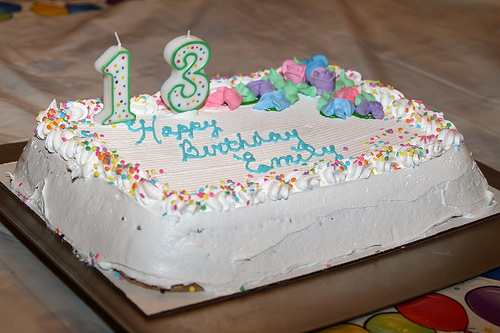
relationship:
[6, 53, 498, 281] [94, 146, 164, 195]
cake with sprinkles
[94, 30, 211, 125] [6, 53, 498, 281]
13 on cake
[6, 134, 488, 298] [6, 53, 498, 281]
frosting on cake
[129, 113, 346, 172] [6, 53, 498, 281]
words on cake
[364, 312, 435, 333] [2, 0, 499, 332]
balloon on table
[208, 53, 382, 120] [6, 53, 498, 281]
roses on cake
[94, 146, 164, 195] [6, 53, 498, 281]
sprinkles on cake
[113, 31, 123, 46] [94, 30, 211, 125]
wicker on 13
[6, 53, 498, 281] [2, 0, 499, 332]
cake on table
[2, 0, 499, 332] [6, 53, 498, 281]
table with cake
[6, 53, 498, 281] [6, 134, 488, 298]
cake with frosting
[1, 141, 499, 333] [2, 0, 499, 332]
cake pan on table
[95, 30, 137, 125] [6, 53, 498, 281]
1 on cake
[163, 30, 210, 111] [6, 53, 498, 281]
3 on cake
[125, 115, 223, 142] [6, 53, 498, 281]
happy on cake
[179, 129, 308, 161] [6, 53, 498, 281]
birthday on cake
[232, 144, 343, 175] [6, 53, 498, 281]
emily on cake